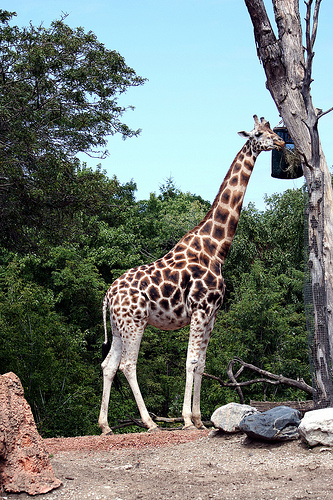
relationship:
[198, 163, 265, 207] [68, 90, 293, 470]
neck of giraffe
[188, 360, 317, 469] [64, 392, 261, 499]
rock on ground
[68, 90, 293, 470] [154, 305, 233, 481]
giraffe has leg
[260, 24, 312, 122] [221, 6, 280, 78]
tree has branch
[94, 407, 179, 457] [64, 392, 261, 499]
dirt on ground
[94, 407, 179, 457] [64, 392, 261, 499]
dirt covering ground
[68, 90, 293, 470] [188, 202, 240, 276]
giraffe has spots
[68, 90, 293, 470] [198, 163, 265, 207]
giraffe has neck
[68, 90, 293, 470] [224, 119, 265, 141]
giraffe has ear